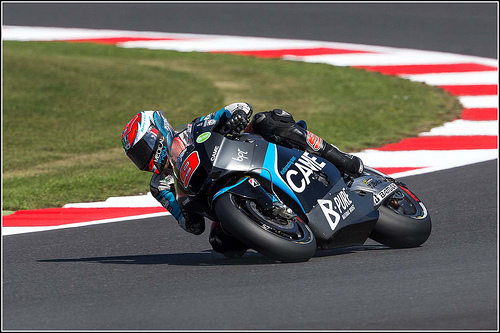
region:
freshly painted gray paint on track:
[95, 270, 194, 297]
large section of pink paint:
[7, 205, 142, 226]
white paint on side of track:
[388, 148, 477, 162]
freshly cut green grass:
[31, 73, 119, 93]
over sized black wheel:
[383, 211, 438, 253]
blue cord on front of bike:
[226, 158, 291, 203]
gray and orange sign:
[167, 150, 207, 179]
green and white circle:
[190, 128, 215, 145]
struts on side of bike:
[237, 178, 315, 227]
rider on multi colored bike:
[112, 94, 476, 261]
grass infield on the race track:
[4, 43, 460, 213]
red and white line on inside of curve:
[4, 25, 498, 240]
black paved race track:
[2, 1, 498, 326]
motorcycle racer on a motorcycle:
[120, 100, 430, 256]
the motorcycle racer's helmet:
[123, 109, 168, 171]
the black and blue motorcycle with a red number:
[180, 130, 431, 253]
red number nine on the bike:
[176, 150, 199, 185]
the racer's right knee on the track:
[207, 225, 234, 251]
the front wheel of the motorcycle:
[216, 188, 315, 261]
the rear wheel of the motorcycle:
[375, 187, 429, 247]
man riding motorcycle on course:
[117, 75, 435, 252]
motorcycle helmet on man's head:
[125, 109, 175, 170]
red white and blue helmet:
[124, 112, 168, 174]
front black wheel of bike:
[215, 186, 322, 261]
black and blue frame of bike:
[200, 132, 303, 179]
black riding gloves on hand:
[217, 108, 251, 133]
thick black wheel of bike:
[366, 183, 438, 245]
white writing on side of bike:
[278, 148, 335, 193]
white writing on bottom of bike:
[311, 188, 363, 225]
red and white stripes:
[426, 105, 491, 175]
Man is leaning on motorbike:
[95, 83, 446, 275]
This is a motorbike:
[180, 113, 423, 259]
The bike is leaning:
[177, 110, 437, 257]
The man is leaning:
[116, 79, 308, 244]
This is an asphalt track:
[27, 186, 498, 328]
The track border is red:
[11, 175, 202, 239]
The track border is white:
[22, 175, 184, 243]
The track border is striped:
[8, 168, 183, 243]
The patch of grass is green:
[7, 40, 419, 182]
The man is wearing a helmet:
[117, 95, 190, 162]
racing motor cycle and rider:
[108, 98, 436, 260]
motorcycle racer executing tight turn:
[108, 95, 436, 263]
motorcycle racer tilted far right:
[111, 95, 436, 261]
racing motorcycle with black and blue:
[116, 93, 437, 263]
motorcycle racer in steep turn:
[113, 98, 258, 260]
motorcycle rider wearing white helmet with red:
[118, 98, 253, 264]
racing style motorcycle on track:
[114, 100, 434, 269]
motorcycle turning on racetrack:
[116, 96, 436, 267]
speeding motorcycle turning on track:
[119, 100, 434, 265]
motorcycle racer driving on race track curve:
[115, 97, 436, 264]